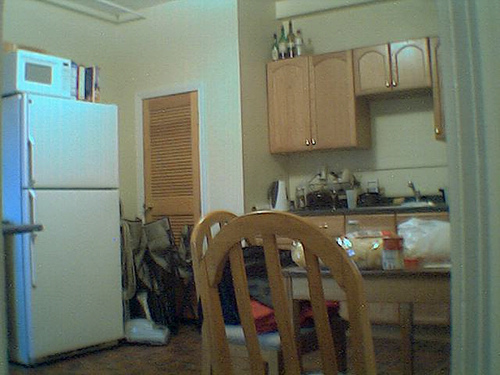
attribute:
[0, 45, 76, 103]
microwave — white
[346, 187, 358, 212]
cup — plastic cup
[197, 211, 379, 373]
chair — wooden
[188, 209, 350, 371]
chair — wooden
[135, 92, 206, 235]
door — small, wooden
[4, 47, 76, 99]
microwave — white, small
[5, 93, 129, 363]
refrigerator — white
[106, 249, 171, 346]
vacuum — upright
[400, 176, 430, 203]
faucet — kitchen sink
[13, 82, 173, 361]
refrigerator — white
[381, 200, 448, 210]
sink — stainless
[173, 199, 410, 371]
wooden chair — light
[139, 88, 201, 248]
door — louvered, wood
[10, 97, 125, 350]
refrigerator — white, two door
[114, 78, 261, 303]
door — light, wooden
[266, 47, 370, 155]
cupboard — kitchen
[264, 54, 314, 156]
door — closed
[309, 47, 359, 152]
door — closed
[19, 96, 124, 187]
freezer — white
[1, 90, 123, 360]
fridge — pictured